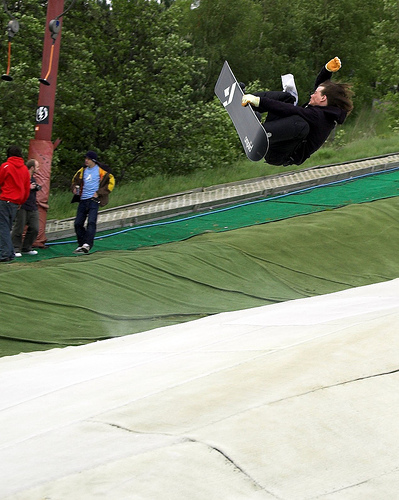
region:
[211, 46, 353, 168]
man performing a snowboarding trick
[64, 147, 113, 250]
man wearing light blue shirt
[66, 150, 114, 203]
man wearing brown and yellow jacket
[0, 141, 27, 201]
man wearing red jacket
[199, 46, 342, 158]
man grabbing snowboard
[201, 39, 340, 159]
man wearing white gloves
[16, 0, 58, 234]
burgundy pole with black and white sticker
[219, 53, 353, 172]
man with long hair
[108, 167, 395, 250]
long blue hose on green mats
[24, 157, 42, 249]
man holding a camera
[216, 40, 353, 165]
Boy on snowboard in the air.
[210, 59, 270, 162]
Black snowboard with white letetrs and design.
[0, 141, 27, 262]
Boy with red hoodie jacket.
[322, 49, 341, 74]
Yellow glove on right hand.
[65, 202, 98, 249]
Blue jeans on boy.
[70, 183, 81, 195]
Can of soda in boy's hand.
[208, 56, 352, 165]
Boy wearing all black on snowboard.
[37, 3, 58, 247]
Large rusty pole.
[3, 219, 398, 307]
Green side area to stand on.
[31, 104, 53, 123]
White lightening symbol on post.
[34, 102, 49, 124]
a black and white sign on a post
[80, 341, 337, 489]
white flooring for skateboarding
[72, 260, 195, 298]
green material used as cushioning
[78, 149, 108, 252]
a man in a blue shirt and coat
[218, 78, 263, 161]
a black and white skateboard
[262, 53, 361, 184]
a person with brown hair doing a skateboard trick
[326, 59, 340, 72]
a yellow glove on a skateboarder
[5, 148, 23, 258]
the back of a man wearing a red hoodie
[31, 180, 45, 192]
a black camera in someone's hands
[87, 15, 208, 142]
a group of trees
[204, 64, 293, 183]
Person holding onto black board.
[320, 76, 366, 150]
Person has dark hair.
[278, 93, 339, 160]
Person wearing black shirt.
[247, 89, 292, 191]
Person wearing black pants.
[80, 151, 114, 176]
Person wearing black hat.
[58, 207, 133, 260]
Person wearing dark pants.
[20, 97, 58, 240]
Large reddish brown pole near people.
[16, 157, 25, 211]
Person wearing red sweatshirt.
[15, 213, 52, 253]
Person wearing dark pants.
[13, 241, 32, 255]
Person wearing white shoes.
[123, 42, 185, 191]
The dark green trees in the background look healthy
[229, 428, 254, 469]
There is a silver color that looks to be below the skateboard jump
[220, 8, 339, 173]
This man is wearing a black sweatshirt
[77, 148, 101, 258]
This man is wearing a very black hat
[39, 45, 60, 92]
The color of this pole is a very deep red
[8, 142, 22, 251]
This man is wearing a very bright red sweatshirt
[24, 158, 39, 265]
This man is wearing a black sweatshirt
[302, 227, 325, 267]
There is a very deep green tarp that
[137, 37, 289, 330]
This photo was taken in the state of Wisconsin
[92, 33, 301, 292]
This photo was taken in the city of Madison